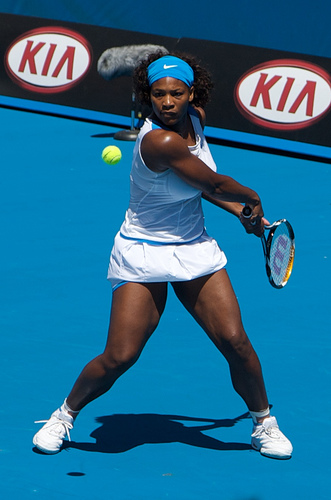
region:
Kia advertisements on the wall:
[12, 16, 330, 172]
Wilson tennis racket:
[226, 187, 310, 299]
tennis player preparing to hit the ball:
[75, 41, 294, 391]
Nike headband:
[128, 49, 217, 87]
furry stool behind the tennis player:
[99, 42, 158, 141]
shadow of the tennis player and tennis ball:
[23, 374, 278, 491]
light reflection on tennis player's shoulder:
[155, 126, 182, 146]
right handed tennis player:
[207, 168, 328, 284]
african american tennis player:
[67, 52, 287, 411]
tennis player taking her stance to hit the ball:
[26, 41, 303, 471]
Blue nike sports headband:
[143, 52, 198, 86]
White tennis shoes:
[244, 409, 292, 461]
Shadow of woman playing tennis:
[87, 407, 252, 470]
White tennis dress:
[123, 128, 232, 283]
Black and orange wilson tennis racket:
[229, 212, 310, 287]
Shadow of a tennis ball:
[68, 470, 83, 477]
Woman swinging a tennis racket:
[125, 56, 291, 397]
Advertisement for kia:
[230, 61, 329, 130]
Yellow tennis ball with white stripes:
[100, 140, 127, 164]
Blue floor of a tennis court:
[19, 259, 71, 336]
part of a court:
[55, 197, 99, 246]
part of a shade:
[152, 413, 177, 440]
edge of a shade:
[108, 428, 138, 455]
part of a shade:
[117, 416, 159, 478]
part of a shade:
[121, 407, 153, 444]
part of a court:
[152, 439, 177, 465]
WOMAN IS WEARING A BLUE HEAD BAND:
[154, 63, 162, 74]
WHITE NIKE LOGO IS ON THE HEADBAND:
[160, 59, 182, 72]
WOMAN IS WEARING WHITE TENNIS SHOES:
[250, 425, 294, 459]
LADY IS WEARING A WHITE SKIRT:
[123, 257, 139, 274]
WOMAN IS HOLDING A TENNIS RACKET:
[248, 203, 301, 296]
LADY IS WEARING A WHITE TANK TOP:
[145, 171, 177, 238]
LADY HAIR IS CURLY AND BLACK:
[193, 69, 201, 85]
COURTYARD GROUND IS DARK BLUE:
[14, 249, 64, 297]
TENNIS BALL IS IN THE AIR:
[107, 144, 119, 163]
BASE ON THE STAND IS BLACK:
[117, 132, 129, 138]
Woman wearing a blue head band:
[125, 52, 226, 155]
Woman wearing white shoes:
[23, 390, 305, 482]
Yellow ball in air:
[94, 135, 138, 180]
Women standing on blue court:
[73, 45, 275, 484]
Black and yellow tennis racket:
[232, 191, 314, 295]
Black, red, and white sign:
[3, 9, 319, 157]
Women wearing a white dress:
[82, 52, 262, 311]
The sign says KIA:
[8, 23, 83, 92]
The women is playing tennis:
[90, 35, 292, 468]